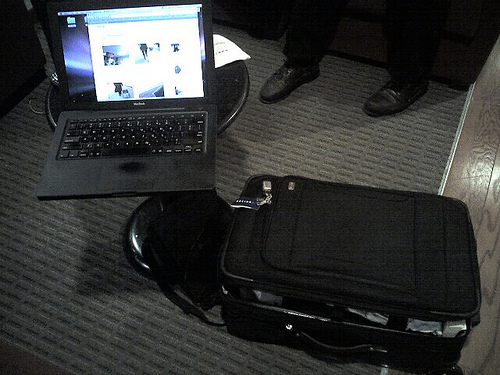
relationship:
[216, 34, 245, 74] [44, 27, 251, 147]
paper on tray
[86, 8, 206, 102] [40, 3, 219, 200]
page on computer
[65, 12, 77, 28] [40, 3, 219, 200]
icon on computer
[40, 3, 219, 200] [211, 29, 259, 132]
computer on table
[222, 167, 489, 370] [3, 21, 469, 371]
luggage on floor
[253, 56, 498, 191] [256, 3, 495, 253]
shoes on person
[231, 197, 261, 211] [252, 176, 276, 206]
tags on zipper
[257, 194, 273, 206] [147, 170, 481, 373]
zipper on luggage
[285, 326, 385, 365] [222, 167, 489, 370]
handle on luggage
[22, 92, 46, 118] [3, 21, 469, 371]
cord on floor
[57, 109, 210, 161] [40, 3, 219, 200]
keyboard on computer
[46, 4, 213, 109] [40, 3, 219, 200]
screen on computer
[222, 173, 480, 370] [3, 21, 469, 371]
luggage on floor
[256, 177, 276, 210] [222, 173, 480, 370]
lock on luggage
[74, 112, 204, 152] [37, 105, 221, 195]
keys on keyboard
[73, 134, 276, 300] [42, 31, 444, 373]
shadow on carpet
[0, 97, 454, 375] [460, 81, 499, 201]
carpet on floor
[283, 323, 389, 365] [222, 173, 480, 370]
handle on luggage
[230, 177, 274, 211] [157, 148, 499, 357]
tags on suitcase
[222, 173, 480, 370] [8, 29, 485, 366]
luggage on ground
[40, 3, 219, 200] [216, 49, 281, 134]
computer on table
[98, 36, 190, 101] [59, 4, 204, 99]
pictures on screen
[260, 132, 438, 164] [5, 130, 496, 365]
carpet on floor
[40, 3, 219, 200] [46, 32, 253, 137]
computer on table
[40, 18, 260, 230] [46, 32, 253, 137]
computer on table